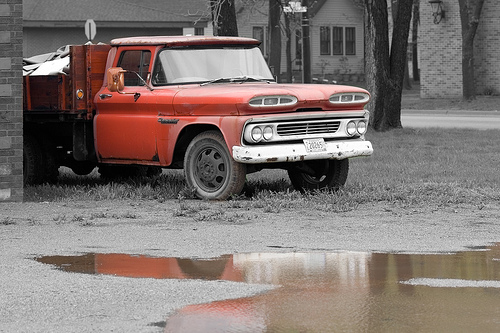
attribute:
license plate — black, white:
[299, 136, 334, 156]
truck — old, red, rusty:
[20, 26, 393, 218]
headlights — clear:
[239, 120, 368, 142]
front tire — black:
[181, 126, 246, 203]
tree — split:
[360, 2, 423, 133]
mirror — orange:
[103, 65, 155, 101]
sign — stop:
[72, 15, 108, 43]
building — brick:
[413, 2, 499, 104]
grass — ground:
[398, 124, 499, 204]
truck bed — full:
[20, 35, 110, 182]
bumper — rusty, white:
[224, 137, 375, 169]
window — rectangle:
[330, 25, 347, 58]